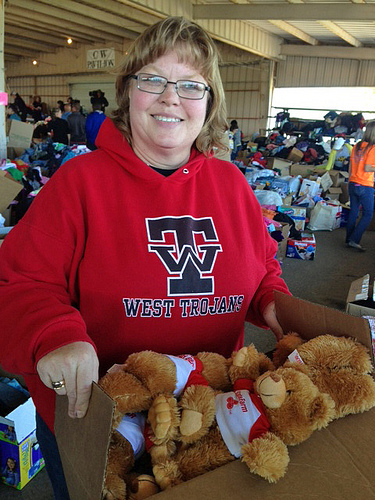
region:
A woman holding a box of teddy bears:
[12, 16, 370, 497]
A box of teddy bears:
[60, 321, 373, 483]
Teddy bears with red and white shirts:
[154, 346, 332, 458]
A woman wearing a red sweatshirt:
[9, 2, 303, 372]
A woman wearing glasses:
[8, 12, 274, 187]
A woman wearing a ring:
[47, 368, 78, 404]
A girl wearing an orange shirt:
[340, 114, 373, 247]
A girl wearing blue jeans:
[341, 111, 372, 253]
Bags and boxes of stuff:
[243, 117, 356, 284]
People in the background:
[11, 69, 116, 170]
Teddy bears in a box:
[101, 334, 350, 454]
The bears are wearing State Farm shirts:
[210, 380, 272, 450]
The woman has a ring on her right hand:
[38, 361, 77, 397]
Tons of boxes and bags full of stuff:
[250, 106, 356, 258]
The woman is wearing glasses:
[116, 56, 231, 110]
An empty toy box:
[1, 400, 43, 481]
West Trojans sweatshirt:
[100, 192, 260, 334]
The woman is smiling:
[117, 34, 227, 157]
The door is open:
[262, 67, 371, 128]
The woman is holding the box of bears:
[26, 310, 355, 474]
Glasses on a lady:
[137, 69, 213, 102]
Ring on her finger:
[50, 377, 65, 391]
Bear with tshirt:
[164, 360, 354, 475]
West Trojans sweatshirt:
[114, 284, 260, 322]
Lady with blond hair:
[124, 14, 225, 167]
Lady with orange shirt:
[345, 113, 372, 254]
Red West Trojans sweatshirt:
[55, 150, 280, 354]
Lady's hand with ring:
[24, 343, 109, 418]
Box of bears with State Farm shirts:
[50, 299, 374, 497]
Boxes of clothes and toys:
[254, 141, 331, 220]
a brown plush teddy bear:
[152, 346, 332, 487]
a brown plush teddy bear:
[271, 329, 371, 423]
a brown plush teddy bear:
[97, 341, 232, 449]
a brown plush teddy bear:
[100, 420, 150, 491]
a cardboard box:
[49, 285, 372, 497]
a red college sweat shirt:
[9, 121, 290, 418]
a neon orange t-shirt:
[347, 138, 372, 185]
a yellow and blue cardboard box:
[4, 391, 37, 487]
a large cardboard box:
[283, 230, 315, 260]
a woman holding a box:
[6, 18, 370, 495]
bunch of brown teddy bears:
[75, 322, 364, 498]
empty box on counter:
[0, 368, 41, 489]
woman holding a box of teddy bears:
[4, 10, 366, 487]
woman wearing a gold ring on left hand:
[3, 216, 89, 459]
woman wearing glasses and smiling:
[114, 8, 240, 164]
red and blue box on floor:
[289, 231, 321, 257]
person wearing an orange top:
[343, 120, 374, 250]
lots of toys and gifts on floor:
[2, 85, 374, 291]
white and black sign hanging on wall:
[84, 39, 117, 76]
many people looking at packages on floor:
[5, 59, 374, 302]